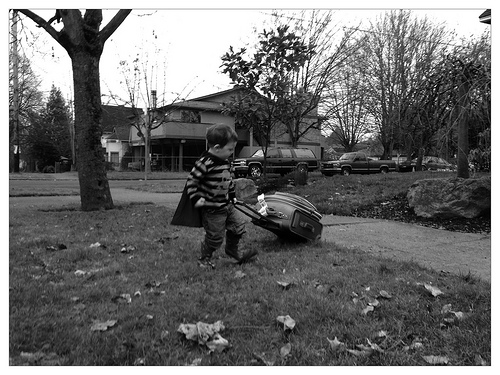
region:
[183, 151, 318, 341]
A boy dragging a trolley.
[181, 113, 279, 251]
A boy dragging a trolley.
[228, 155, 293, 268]
A boy dragging a trolley.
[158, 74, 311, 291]
A boy dragging a trolley.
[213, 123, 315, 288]
A boy dragging a trolley.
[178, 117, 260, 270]
little boy playing outside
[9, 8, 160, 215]
a tree that has lost all its leaves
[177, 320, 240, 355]
brown leaves on the ground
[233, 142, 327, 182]
station wagon parked in driveway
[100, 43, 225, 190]
A tree with a few leaves left on it.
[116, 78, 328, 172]
house in the background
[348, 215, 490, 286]
sidewalk that parrells the street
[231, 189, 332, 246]
object that the boy is pulling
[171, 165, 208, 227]
a garbage bag that is half hidden behind the boy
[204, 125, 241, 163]
the boys hair is brown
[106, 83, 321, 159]
a big house across the street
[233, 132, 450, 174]
the cars parked on the street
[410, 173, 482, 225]
the rock by the sidewalk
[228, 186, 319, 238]
the suitcase the boy is holding onto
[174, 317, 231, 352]
a leaf on the ground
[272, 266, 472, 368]
more leaves on the ground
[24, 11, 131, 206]
the tree in the front yard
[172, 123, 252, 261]
the boy in the yard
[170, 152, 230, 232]
the cape the boy is wearing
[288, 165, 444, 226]
some more grass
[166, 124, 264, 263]
a little boy in a cape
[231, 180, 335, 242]
a suitcase pulled by a little boy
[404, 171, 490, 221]
a large rock along a sidewalk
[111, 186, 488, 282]
a sidewalk in a yard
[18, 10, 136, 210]
abrown tree trunk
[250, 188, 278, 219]
a white tag on a suitcase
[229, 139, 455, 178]
vehicles parked along a road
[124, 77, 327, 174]
a house by a road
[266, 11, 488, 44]
a telephone wire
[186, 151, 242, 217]
a striped shirt on a little boy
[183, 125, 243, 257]
a boy standing in the front yard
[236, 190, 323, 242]
a suitcase that the boy is holding onto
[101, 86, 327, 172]
a house across the street from the boy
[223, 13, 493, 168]
the trees standing along the street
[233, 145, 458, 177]
the cars parked next to the street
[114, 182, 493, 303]
the sidewalk next to the suitcase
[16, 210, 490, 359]
the yard the boy is walking in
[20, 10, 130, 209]
the tree standing in the yard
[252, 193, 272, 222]
the tag on the suitcse